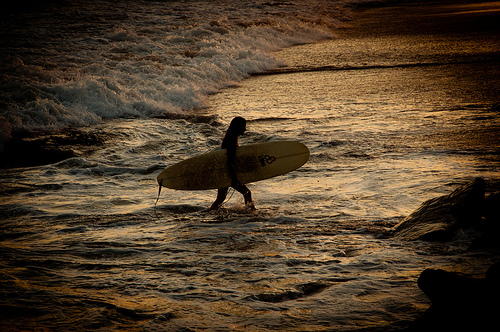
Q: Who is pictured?
A: Surfer.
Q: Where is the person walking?
A: In the water.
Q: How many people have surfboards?
A: 1.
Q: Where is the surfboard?
A: In the person's arm.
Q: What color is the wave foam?
A: White.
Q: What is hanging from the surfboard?
A: A tether.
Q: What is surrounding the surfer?
A: Water.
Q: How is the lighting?
A: Dark.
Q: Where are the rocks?
A: On the right.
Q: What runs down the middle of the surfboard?
A: A line.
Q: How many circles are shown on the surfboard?
A: 3.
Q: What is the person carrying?
A: A surfboard.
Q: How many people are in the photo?
A: 1.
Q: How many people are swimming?
A: None.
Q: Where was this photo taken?
A: At the ocean.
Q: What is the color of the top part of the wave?
A: White.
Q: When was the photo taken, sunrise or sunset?
A: Sunset.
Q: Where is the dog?
A: There isn't one.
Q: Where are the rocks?
A: On the right side of the picture.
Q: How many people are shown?
A: One.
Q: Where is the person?
A: In the water.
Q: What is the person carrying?
A: Surfboard.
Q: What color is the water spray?
A: White.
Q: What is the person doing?
A: Walking.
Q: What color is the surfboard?
A: Yellow with black.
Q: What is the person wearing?
A: Wetsuit.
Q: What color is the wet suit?
A: Black.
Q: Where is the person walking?
A: Out of the water.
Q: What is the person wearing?
A: A wetsuit.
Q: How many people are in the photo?
A: One.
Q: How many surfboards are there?
A: One.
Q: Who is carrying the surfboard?
A: The surfer.